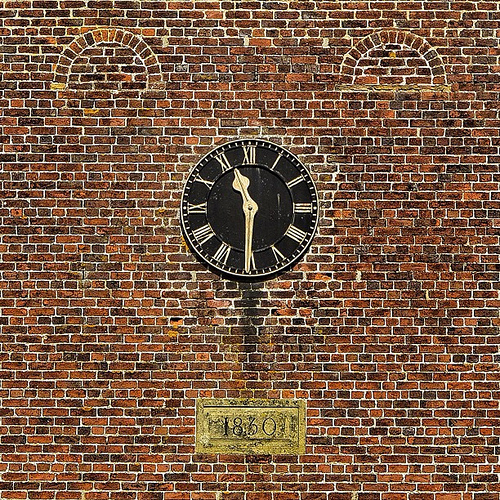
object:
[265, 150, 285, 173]
number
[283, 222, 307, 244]
number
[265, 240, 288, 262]
number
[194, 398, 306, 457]
year plate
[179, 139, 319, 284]
black clock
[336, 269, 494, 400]
bricks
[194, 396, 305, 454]
container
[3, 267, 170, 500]
bricks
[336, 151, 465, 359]
dust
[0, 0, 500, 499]
wall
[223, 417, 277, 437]
inscription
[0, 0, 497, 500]
building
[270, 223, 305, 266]
roman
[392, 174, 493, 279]
bricks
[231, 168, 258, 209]
hand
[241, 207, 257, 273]
hand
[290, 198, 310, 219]
number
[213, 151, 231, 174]
number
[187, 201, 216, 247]
roman numerals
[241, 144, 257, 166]
number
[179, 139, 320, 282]
clock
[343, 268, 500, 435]
brown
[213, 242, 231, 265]
number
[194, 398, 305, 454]
gold background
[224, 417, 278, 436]
1860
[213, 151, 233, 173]
numerals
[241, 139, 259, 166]
marks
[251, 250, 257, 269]
numeral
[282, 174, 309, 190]
number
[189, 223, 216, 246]
number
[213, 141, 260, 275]
11:30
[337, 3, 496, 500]
bricks